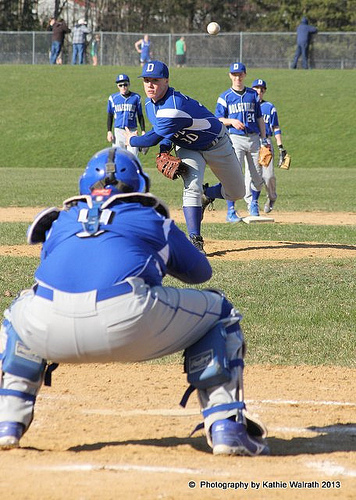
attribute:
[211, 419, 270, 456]
shoe — Blue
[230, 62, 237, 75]
cap — blue 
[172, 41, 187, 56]
shirt — green 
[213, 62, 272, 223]
baseball player — white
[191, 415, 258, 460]
heel — blue 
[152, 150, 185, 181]
glove — light brown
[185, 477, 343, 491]
copyright — Black 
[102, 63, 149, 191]
uniform — white, blue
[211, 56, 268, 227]
uniform — white, blue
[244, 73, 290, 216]
uniform — white, blue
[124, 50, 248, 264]
uniform — white, blue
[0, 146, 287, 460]
uniform — white, blue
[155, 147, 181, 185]
glove — brown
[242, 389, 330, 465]
outline — white 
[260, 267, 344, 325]
grass — Green 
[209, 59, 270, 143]
baseball player — blue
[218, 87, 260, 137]
uniform — white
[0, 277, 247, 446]
pants — Gray 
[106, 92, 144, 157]
uniform — blue, white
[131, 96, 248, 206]
uniform — white, blue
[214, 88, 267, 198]
uniform — blue, white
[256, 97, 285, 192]
uniform — white, blue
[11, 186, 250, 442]
uniform — blue, white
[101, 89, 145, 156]
uniform — white, blue